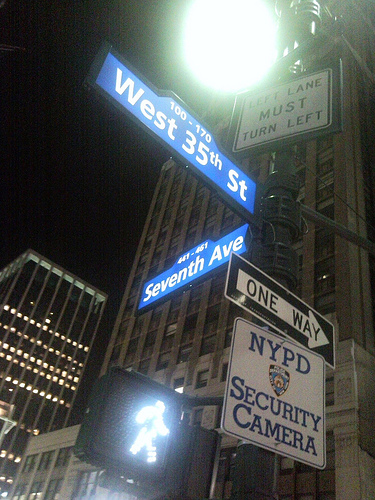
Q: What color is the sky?
A: Black.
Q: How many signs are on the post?
A: Five.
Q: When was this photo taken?
A: Outside, during the night.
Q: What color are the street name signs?
A: Blue.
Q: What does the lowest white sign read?
A: NYPD Security Camera.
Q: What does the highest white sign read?
A: Left Lane Must Turn Left.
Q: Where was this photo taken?
A: At a sign pole.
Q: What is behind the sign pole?
A: A building.